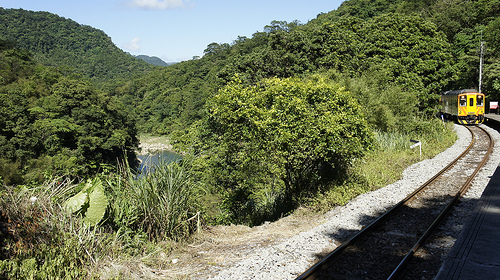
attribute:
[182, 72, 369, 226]
bush — fluffy green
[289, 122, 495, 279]
railroad tracks — rusty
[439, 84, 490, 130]
train car — yellow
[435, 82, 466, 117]
train car — black, yellow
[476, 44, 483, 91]
pole — utility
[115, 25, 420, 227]
trees — lining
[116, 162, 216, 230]
bush — fluffy, green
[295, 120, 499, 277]
track — rusty, under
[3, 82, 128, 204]
bush — fluffy, green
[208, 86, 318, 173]
leaf — wide, green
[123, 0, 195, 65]
clouds — wispy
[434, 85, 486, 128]
train — yellow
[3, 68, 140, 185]
bush — green, fluffy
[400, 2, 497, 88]
bush — green, fluffy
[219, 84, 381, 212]
bush — green, fluffy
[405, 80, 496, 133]
train — yellow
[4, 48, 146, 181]
tree — green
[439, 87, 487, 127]
train — ON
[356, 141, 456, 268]
tracks — rusted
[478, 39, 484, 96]
pole — wooden